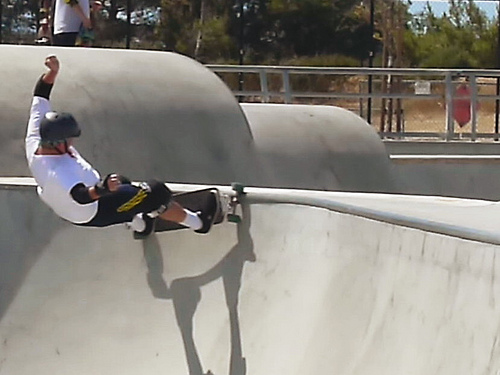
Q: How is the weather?
A: Warm.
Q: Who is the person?
A: A man.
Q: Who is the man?
A: Skateboarder.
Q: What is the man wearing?
A: Helmet.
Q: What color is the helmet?
A: Black.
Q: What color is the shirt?
A: White.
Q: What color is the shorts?
A: Navy.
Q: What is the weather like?
A: Sunny.